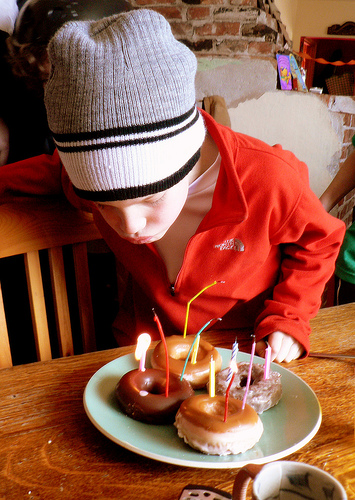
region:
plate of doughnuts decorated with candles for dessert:
[81, 274, 316, 458]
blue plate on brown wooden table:
[4, 305, 349, 492]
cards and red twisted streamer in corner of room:
[274, 4, 351, 96]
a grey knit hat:
[29, 6, 220, 187]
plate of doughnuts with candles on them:
[73, 276, 339, 459]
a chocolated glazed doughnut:
[117, 367, 194, 424]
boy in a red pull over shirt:
[2, 74, 337, 358]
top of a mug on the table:
[216, 459, 353, 499]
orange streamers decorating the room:
[295, 46, 354, 70]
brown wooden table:
[4, 448, 113, 497]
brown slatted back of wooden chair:
[0, 199, 134, 345]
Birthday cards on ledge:
[267, 46, 317, 90]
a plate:
[274, 412, 306, 434]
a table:
[57, 458, 94, 491]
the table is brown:
[37, 452, 83, 485]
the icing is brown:
[201, 411, 219, 427]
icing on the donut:
[254, 384, 268, 399]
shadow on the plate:
[98, 370, 118, 395]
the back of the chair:
[2, 208, 56, 245]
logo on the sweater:
[213, 239, 255, 253]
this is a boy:
[20, 12, 336, 401]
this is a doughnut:
[182, 381, 271, 455]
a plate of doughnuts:
[87, 275, 315, 470]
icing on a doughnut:
[177, 381, 258, 440]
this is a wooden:
[0, 264, 353, 497]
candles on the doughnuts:
[121, 266, 283, 425]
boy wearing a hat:
[16, 0, 244, 214]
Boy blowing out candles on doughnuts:
[39, 6, 346, 473]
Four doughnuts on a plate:
[84, 331, 323, 467]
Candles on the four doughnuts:
[133, 277, 274, 421]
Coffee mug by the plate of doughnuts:
[228, 461, 349, 497]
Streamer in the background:
[289, 48, 353, 67]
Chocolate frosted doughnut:
[114, 362, 190, 423]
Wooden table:
[0, 300, 353, 498]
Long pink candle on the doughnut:
[241, 333, 257, 420]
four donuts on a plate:
[116, 336, 283, 452]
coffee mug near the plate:
[231, 461, 348, 498]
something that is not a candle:
[182, 277, 225, 340]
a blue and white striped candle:
[226, 339, 238, 382]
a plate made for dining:
[87, 344, 326, 469]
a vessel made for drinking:
[230, 453, 343, 497]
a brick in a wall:
[211, 35, 274, 58]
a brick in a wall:
[178, 35, 212, 52]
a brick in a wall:
[242, 21, 266, 37]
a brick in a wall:
[191, 19, 239, 36]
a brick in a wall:
[210, 5, 261, 21]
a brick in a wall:
[148, 4, 184, 22]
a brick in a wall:
[338, 110, 352, 127]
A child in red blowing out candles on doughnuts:
[42, 9, 333, 470]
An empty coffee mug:
[229, 462, 349, 499]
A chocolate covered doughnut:
[111, 364, 191, 419]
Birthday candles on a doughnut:
[231, 341, 272, 378]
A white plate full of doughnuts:
[78, 334, 325, 467]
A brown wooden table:
[5, 329, 352, 498]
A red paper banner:
[290, 55, 353, 68]